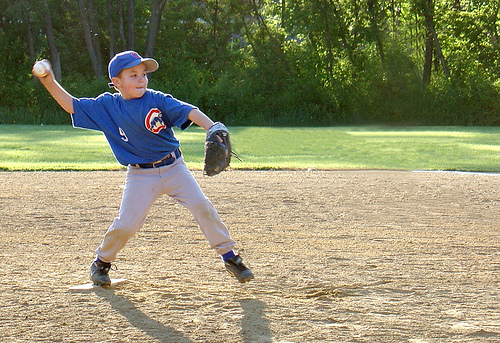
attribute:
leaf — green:
[309, 107, 312, 110]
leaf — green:
[265, 91, 273, 101]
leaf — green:
[396, 79, 405, 88]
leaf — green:
[258, 73, 281, 93]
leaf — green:
[341, 73, 347, 78]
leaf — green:
[364, 91, 367, 96]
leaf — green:
[210, 80, 213, 82]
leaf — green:
[261, 97, 265, 102]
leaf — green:
[333, 94, 337, 101]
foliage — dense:
[5, 2, 493, 122]